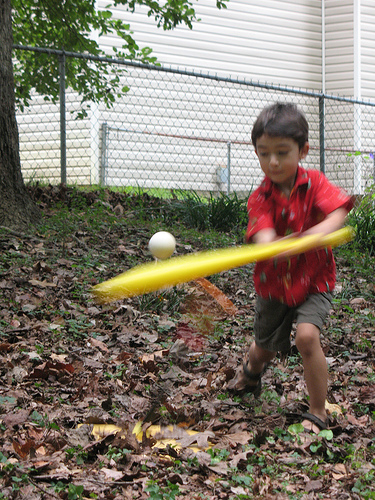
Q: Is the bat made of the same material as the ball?
A: Yes, both the bat and the ball are made of plastic.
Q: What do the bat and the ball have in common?
A: The material, both the bat and the ball are plastic.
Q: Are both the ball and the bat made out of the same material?
A: Yes, both the ball and the bat are made of plastic.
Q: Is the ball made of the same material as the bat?
A: Yes, both the ball and the bat are made of plastic.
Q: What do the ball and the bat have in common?
A: The material, both the ball and the bat are plastic.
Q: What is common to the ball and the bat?
A: The material, both the ball and the bat are plastic.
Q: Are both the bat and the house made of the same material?
A: No, the bat is made of plastic and the house is made of metal.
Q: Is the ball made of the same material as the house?
A: No, the ball is made of plastic and the house is made of metal.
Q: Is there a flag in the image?
A: No, there are no flags.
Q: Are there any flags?
A: No, there are no flags.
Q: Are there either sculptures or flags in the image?
A: No, there are no flags or sculptures.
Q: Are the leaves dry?
A: Yes, the leaves are dry.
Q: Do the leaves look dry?
A: Yes, the leaves are dry.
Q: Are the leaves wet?
A: No, the leaves are dry.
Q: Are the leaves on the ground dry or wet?
A: The leaves are dry.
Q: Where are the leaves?
A: The leaves are on the ground.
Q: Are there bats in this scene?
A: Yes, there is a bat.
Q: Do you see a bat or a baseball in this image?
A: Yes, there is a bat.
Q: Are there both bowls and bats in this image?
A: No, there is a bat but no bowls.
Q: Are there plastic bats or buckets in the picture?
A: Yes, there is a plastic bat.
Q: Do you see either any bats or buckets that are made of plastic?
A: Yes, the bat is made of plastic.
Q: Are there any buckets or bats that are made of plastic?
A: Yes, the bat is made of plastic.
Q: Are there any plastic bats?
A: Yes, there is a bat that is made of plastic.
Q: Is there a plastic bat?
A: Yes, there is a bat that is made of plastic.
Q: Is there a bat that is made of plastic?
A: Yes, there is a bat that is made of plastic.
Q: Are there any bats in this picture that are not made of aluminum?
A: Yes, there is a bat that is made of plastic.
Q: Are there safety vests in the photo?
A: No, there are no safety vests.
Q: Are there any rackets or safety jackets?
A: No, there are no safety jackets or rackets.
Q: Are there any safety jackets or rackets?
A: No, there are no safety jackets or rackets.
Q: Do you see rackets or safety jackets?
A: No, there are no safety jackets or rackets.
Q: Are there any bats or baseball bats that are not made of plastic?
A: No, there is a bat but it is made of plastic.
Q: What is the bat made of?
A: The bat is made of plastic.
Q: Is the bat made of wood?
A: No, the bat is made of plastic.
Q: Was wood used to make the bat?
A: No, the bat is made of plastic.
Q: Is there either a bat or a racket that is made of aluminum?
A: No, there is a bat but it is made of plastic.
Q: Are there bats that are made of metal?
A: No, there is a bat but it is made of plastic.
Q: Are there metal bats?
A: No, there is a bat but it is made of plastic.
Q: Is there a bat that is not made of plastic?
A: No, there is a bat but it is made of plastic.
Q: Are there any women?
A: No, there are no women.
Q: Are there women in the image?
A: No, there are no women.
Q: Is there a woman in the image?
A: No, there are no women.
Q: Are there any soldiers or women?
A: No, there are no women or soldiers.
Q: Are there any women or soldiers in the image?
A: No, there are no women or soldiers.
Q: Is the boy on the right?
A: Yes, the boy is on the right of the image.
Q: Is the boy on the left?
A: No, the boy is on the right of the image.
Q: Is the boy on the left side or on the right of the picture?
A: The boy is on the right of the image.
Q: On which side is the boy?
A: The boy is on the right of the image.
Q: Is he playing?
A: Yes, the boy is playing.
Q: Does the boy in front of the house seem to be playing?
A: Yes, the boy is playing.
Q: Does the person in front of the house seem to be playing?
A: Yes, the boy is playing.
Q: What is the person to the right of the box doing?
A: The boy is playing.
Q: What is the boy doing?
A: The boy is playing.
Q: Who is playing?
A: The boy is playing.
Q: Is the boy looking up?
A: No, the boy is playing.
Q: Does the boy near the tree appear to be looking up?
A: No, the boy is playing.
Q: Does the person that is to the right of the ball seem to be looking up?
A: No, the boy is playing.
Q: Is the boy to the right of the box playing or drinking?
A: The boy is playing.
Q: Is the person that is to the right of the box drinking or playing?
A: The boy is playing.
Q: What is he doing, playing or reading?
A: The boy is playing.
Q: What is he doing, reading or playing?
A: The boy is playing.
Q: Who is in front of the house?
A: The boy is in front of the house.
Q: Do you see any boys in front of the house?
A: Yes, there is a boy in front of the house.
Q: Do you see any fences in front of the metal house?
A: No, there is a boy in front of the house.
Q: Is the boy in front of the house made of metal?
A: Yes, the boy is in front of the house.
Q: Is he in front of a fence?
A: No, the boy is in front of the house.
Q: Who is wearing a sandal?
A: The boy is wearing a sandal.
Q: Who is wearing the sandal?
A: The boy is wearing a sandal.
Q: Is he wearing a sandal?
A: Yes, the boy is wearing a sandal.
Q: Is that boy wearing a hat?
A: No, the boy is wearing a sandal.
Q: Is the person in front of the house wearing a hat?
A: No, the boy is wearing a sandal.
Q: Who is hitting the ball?
A: The boy is hitting the ball.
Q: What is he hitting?
A: The boy is hitting the ball.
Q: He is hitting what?
A: The boy is hitting the ball.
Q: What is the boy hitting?
A: The boy is hitting the ball.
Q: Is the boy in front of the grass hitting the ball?
A: Yes, the boy is hitting the ball.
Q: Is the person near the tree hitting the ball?
A: Yes, the boy is hitting the ball.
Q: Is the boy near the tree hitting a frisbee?
A: No, the boy is hitting the ball.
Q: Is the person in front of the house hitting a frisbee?
A: No, the boy is hitting the ball.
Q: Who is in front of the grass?
A: The boy is in front of the grass.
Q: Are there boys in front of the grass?
A: Yes, there is a boy in front of the grass.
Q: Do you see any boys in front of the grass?
A: Yes, there is a boy in front of the grass.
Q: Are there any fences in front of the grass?
A: No, there is a boy in front of the grass.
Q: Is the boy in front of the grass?
A: Yes, the boy is in front of the grass.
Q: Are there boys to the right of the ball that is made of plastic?
A: Yes, there is a boy to the right of the ball.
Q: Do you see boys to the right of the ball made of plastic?
A: Yes, there is a boy to the right of the ball.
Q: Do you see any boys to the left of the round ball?
A: No, the boy is to the right of the ball.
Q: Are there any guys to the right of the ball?
A: No, there is a boy to the right of the ball.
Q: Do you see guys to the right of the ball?
A: No, there is a boy to the right of the ball.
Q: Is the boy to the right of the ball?
A: Yes, the boy is to the right of the ball.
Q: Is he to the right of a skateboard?
A: No, the boy is to the right of the ball.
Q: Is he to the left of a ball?
A: No, the boy is to the right of a ball.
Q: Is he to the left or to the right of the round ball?
A: The boy is to the right of the ball.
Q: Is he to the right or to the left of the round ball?
A: The boy is to the right of the ball.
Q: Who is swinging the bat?
A: The boy is swinging the bat.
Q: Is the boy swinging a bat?
A: Yes, the boy is swinging a bat.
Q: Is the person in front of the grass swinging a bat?
A: Yes, the boy is swinging a bat.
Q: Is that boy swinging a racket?
A: No, the boy is swinging a bat.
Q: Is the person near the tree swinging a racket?
A: No, the boy is swinging a bat.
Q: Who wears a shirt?
A: The boy wears a shirt.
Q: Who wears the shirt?
A: The boy wears a shirt.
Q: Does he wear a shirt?
A: Yes, the boy wears a shirt.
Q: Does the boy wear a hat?
A: No, the boy wears a shirt.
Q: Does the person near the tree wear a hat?
A: No, the boy wears a shirt.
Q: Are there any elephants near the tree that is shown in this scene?
A: No, there is a boy near the tree.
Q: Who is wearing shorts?
A: The boy is wearing shorts.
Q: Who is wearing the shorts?
A: The boy is wearing shorts.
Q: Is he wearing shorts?
A: Yes, the boy is wearing shorts.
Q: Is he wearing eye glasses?
A: No, the boy is wearing shorts.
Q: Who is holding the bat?
A: The boy is holding the bat.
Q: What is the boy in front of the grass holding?
A: The boy is holding the bat.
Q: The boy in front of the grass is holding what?
A: The boy is holding the bat.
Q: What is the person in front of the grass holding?
A: The boy is holding the bat.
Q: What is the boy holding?
A: The boy is holding the bat.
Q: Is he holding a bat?
A: Yes, the boy is holding a bat.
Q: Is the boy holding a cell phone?
A: No, the boy is holding a bat.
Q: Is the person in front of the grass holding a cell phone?
A: No, the boy is holding a bat.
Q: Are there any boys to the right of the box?
A: Yes, there is a boy to the right of the box.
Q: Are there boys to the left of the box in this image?
A: No, the boy is to the right of the box.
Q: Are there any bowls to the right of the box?
A: No, there is a boy to the right of the box.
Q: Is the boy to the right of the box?
A: Yes, the boy is to the right of the box.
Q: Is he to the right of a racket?
A: No, the boy is to the right of the box.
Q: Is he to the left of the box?
A: No, the boy is to the right of the box.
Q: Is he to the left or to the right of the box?
A: The boy is to the right of the box.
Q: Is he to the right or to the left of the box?
A: The boy is to the right of the box.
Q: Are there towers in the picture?
A: No, there are no towers.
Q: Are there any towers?
A: No, there are no towers.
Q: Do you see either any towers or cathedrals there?
A: No, there are no towers or cathedrals.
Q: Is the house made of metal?
A: Yes, the house is made of metal.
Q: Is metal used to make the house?
A: Yes, the house is made of metal.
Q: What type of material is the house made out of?
A: The house is made of metal.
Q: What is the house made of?
A: The house is made of metal.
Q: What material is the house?
A: The house is made of metal.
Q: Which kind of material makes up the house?
A: The house is made of metal.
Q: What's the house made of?
A: The house is made of metal.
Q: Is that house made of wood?
A: No, the house is made of metal.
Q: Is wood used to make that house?
A: No, the house is made of metal.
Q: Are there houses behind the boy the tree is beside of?
A: Yes, there is a house behind the boy.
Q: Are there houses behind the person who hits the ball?
A: Yes, there is a house behind the boy.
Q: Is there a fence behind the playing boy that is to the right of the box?
A: No, there is a house behind the boy.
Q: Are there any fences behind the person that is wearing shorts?
A: No, there is a house behind the boy.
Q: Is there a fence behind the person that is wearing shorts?
A: No, there is a house behind the boy.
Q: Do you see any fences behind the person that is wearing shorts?
A: No, there is a house behind the boy.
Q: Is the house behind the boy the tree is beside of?
A: Yes, the house is behind the boy.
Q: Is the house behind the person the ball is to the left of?
A: Yes, the house is behind the boy.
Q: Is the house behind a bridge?
A: No, the house is behind the boy.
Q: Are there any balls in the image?
A: Yes, there is a ball.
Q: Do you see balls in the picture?
A: Yes, there is a ball.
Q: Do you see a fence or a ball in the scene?
A: Yes, there is a ball.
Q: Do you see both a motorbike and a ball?
A: No, there is a ball but no motorcycles.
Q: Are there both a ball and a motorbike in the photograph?
A: No, there is a ball but no motorcycles.